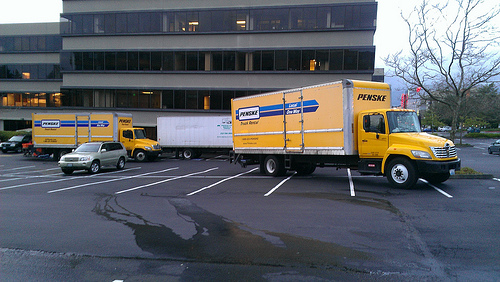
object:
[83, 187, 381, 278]
water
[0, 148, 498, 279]
ground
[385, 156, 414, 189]
wheels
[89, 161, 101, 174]
wheels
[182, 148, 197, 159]
wheels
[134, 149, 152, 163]
wheels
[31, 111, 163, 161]
truck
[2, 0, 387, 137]
building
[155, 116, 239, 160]
truck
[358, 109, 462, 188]
front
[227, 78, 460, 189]
truck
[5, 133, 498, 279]
parking lot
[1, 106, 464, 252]
area